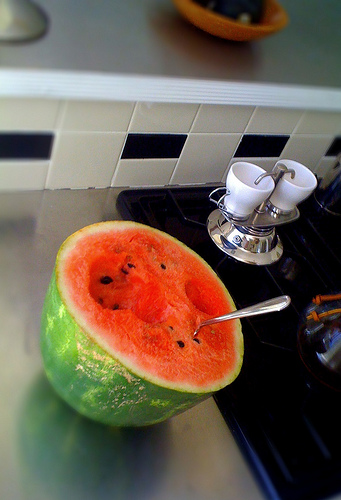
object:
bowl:
[171, 1, 286, 42]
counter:
[0, 0, 341, 112]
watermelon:
[38, 221, 245, 433]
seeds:
[100, 272, 114, 285]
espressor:
[208, 159, 318, 264]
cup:
[225, 162, 276, 219]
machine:
[208, 163, 301, 265]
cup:
[269, 159, 317, 214]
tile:
[1, 129, 55, 162]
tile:
[118, 130, 188, 159]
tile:
[234, 133, 291, 159]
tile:
[325, 134, 341, 157]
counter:
[0, 186, 276, 499]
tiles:
[60, 99, 138, 133]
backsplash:
[0, 94, 340, 190]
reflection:
[223, 236, 264, 258]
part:
[264, 295, 292, 314]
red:
[62, 227, 241, 383]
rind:
[60, 335, 120, 403]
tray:
[115, 186, 341, 500]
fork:
[192, 294, 291, 336]